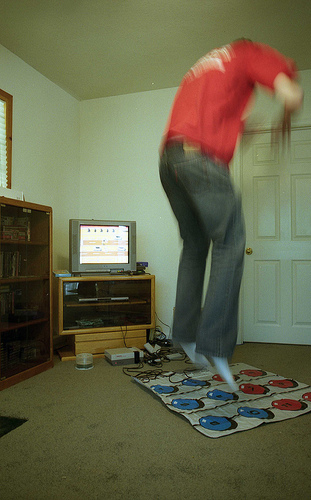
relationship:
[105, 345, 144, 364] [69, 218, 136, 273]
video game console under tv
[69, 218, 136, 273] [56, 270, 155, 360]
tv placed atop of cabinet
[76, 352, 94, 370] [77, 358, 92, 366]
holder of cd's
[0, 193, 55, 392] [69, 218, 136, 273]
bookcase next to tv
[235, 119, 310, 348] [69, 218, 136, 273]
door next to tv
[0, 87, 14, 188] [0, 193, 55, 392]
window above bookcase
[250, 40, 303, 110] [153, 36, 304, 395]
arm of man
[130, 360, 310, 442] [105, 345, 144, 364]
game pad for video game console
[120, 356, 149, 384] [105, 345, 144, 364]
cord for video game console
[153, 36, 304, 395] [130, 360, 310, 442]
man juming on game pad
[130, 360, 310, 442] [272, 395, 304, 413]
game pad has button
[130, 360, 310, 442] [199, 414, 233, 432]
game pad has circle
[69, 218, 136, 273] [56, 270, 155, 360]
tv set on top of cabinet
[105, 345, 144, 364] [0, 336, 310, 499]
video game console sat on carpet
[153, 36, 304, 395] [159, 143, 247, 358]
man wearing jeans